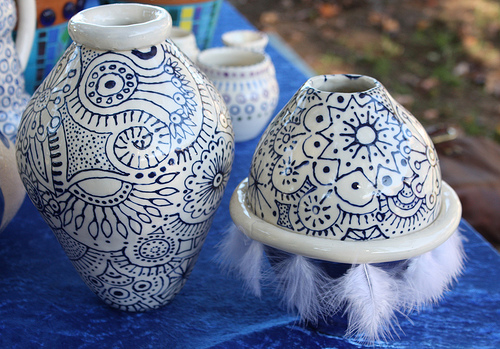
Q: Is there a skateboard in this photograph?
A: No, there are no skateboards.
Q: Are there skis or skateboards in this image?
A: No, there are no skateboards or skis.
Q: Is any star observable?
A: Yes, there is a star.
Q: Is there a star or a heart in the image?
A: Yes, there is a star.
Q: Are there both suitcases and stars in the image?
A: No, there is a star but no suitcases.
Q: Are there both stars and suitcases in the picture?
A: No, there is a star but no suitcases.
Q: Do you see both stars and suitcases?
A: No, there is a star but no suitcases.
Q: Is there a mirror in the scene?
A: No, there are no mirrors.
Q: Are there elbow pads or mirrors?
A: No, there are no mirrors or elbow pads.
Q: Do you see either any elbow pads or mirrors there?
A: No, there are no mirrors or elbow pads.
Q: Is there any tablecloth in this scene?
A: Yes, there is a tablecloth.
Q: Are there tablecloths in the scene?
A: Yes, there is a tablecloth.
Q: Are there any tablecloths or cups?
A: Yes, there is a tablecloth.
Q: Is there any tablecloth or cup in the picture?
A: Yes, there is a tablecloth.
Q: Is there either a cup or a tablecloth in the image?
A: Yes, there is a tablecloth.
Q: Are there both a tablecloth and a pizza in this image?
A: No, there is a tablecloth but no pizzas.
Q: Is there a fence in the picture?
A: No, there are no fences.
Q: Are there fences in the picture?
A: No, there are no fences.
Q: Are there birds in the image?
A: No, there are no birds.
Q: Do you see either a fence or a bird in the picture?
A: No, there are no birds or fences.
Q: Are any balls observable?
A: No, there are no balls.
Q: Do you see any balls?
A: No, there are no balls.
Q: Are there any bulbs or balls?
A: No, there are no balls or bulbs.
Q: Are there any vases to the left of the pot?
A: Yes, there is a vase to the left of the pot.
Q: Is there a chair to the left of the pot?
A: No, there is a vase to the left of the pot.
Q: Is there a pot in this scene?
A: Yes, there is a pot.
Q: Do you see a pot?
A: Yes, there is a pot.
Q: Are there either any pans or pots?
A: Yes, there is a pot.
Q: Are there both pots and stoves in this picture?
A: No, there is a pot but no stoves.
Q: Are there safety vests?
A: No, there are no safety vests.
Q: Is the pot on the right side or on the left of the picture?
A: The pot is on the left of the image.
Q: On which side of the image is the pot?
A: The pot is on the left of the image.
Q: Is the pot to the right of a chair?
A: No, the pot is to the right of a vase.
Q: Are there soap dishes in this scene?
A: No, there are no soap dishes.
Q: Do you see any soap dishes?
A: No, there are no soap dishes.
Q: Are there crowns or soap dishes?
A: No, there are no soap dishes or crowns.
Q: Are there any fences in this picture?
A: No, there are no fences.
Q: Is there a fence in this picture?
A: No, there are no fences.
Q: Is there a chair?
A: No, there are no chairs.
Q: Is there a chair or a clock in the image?
A: No, there are no chairs or clocks.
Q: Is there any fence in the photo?
A: No, there are no fences.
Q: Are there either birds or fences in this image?
A: No, there are no fences or birds.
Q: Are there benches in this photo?
A: No, there are no benches.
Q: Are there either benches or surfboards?
A: No, there are no benches or surfboards.